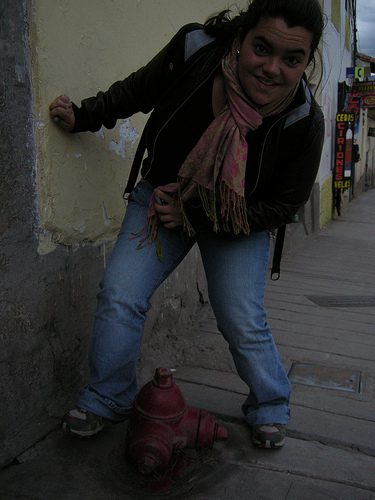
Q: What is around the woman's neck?
A: A pink scarve.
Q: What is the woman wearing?
A: Blue jeans.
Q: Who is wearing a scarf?
A: A lady.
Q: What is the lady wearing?
A: A black shirt.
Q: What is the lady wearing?
A: A black jacket.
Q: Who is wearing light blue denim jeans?
A: A lady.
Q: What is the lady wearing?
A: Tennis shoes.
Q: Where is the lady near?
A: A red fire hydrant.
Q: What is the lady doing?
A: Leaning to the side.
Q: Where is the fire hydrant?
A: Under the woman.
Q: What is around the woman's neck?
A: Scarf.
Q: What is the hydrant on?
A: The sidewalk.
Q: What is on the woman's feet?
A: Shoes.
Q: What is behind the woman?
A: Yellow wall.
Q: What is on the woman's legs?
A: Jeans.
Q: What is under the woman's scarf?
A: Jacket.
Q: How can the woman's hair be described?
A: Long and curly.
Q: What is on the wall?
A: Lady's hand.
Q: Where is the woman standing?
A: Over the fire hydrant.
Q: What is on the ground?
A: A red fire hydrant.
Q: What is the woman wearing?
A: Blue jeans.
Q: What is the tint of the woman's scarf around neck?
A: Pink and green.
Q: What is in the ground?
A: A fire hydrant.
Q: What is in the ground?
A: A hydrant.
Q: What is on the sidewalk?
A: A fire hydrant.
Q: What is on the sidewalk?
A: A hydrant.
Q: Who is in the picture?
A: A woman.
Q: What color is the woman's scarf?
A: Pink.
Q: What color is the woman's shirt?
A: Black.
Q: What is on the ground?
A: Fire hydrant.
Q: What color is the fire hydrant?
A: Red.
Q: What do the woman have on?
A: Jeans.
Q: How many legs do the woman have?
A: Two.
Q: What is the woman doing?
A: Bending.